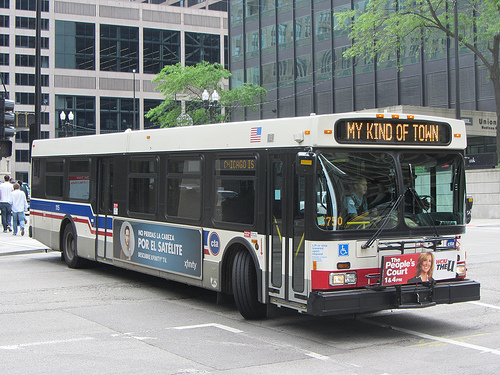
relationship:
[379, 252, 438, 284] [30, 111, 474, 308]
banner mounted on bus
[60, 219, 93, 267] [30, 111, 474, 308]
tire mounted on bus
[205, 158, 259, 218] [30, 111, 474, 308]
window built into bus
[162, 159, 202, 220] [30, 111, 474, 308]
window built into bus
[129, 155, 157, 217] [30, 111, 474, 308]
window built into bus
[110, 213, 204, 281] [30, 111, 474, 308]
banner mounted on bus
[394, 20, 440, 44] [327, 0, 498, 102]
branch growing on tree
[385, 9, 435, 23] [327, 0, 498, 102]
branch growing on tree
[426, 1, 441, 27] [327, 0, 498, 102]
branch growing on tree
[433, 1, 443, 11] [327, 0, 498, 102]
branch growing on tree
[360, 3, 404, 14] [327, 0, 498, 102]
branch growing on tree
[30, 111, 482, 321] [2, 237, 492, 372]
bus parked on street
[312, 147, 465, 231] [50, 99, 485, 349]
windshield belonging to bus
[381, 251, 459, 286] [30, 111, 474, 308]
banner mounted on bus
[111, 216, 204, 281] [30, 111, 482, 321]
banner mounted on bus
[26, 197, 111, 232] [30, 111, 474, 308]
stripe painted on bus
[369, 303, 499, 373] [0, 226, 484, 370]
line painted on ground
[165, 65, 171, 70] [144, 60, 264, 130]
leaf hanging from tree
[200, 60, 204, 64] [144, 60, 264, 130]
leaf hanging from tree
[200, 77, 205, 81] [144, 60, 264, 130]
leaf hanging from tree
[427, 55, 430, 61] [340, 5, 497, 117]
leaf hanging from tree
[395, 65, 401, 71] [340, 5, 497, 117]
leaf hanging from tree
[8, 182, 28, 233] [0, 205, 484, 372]
person walking on street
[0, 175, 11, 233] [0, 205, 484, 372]
person walking on street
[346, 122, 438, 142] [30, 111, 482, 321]
orange letter lit up on bus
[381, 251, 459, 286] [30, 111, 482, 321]
banner painted on bus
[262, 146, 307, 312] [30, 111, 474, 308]
doors leading to bus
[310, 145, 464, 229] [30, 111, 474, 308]
window belonging to bus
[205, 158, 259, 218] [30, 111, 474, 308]
window belonging to bus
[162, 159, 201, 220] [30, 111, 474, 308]
window belonging to bus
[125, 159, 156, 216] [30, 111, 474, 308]
window belonging to bus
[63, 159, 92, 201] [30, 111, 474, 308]
window belonging to bus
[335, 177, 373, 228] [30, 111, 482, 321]
driver sitting in bus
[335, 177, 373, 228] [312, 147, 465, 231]
driver sitting behind windshield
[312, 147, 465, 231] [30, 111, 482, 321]
windshield belonging to bus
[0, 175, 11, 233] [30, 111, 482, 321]
person walking away from bus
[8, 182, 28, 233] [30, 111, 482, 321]
person walking away from bus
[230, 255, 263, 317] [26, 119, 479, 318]
tire of bus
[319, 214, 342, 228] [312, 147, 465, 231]
number in windshield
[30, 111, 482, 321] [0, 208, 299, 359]
bus on road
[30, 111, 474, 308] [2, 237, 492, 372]
bus on street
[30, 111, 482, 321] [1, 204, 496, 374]
bus on road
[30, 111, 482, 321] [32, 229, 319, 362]
bus on road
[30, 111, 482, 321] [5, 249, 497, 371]
bus on road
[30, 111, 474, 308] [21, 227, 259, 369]
bus on road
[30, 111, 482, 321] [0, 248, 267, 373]
bus on road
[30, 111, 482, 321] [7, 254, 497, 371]
bus on street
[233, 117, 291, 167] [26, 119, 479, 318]
sticker on bus